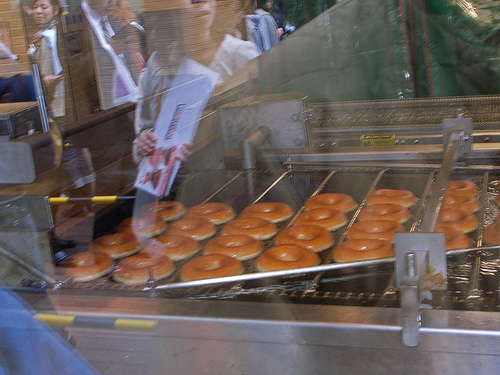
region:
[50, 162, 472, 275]
donuts on a conveyer belt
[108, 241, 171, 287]
plane glazed donut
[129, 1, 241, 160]
lady looking at the donuts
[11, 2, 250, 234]
people reflected on the glass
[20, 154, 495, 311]
conveyer belt for the donuts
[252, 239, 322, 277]
fresh plain glazed donut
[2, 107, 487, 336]
machine for making donuts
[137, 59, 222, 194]
box in the woman's hand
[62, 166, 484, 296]
donuts are ready to be bought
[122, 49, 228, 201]
donut box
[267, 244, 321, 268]
donut on the tray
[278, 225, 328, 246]
donut on the tray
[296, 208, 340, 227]
donut on the tray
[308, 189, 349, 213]
donut on the tray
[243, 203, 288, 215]
donut on the tray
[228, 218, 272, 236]
donut on the tray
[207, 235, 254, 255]
donut on the tray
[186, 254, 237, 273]
donut on the tray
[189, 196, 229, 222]
donut on the tray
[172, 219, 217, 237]
donut on the tray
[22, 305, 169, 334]
yellow and black handle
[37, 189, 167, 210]
yellow and black metal bar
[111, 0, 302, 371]
woman standing near reflective window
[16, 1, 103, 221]
woman standing on street near reflective window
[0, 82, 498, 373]
large metal doughnut making machine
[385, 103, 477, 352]
metal bar on top of doughnut making machine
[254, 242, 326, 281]
brown and light yellow doughnut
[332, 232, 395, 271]
brown doughnut on conveyor belt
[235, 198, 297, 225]
brown and light yellow doughnut on conveyor belt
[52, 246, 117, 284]
brown and light yellow doughnut on conveyor belt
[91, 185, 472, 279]
Delicious glazed donuts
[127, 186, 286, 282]
The donuts are fried in rows of four.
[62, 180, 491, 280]
twenty four glazed donuts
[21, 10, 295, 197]
Reflection of people in the window.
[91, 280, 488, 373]
Stainless steel fryer is shown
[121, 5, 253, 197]
The person is holding a box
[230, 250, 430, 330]
The fryer is full of oil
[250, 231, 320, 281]
the donuts are round with a hole in the center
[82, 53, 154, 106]
A purple triangle is at the top left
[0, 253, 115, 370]
Blue reflection in corner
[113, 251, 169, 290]
the donut is brown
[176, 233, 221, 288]
the donut is brown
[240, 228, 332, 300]
the donut is brown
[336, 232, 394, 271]
the donut is brown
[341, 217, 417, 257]
the donut is brown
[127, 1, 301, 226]
reflection of a woman